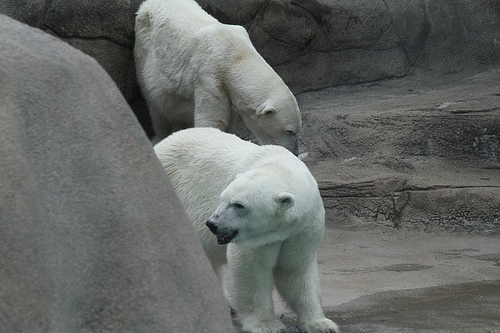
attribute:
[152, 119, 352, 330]
bear — white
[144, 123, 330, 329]
bear — white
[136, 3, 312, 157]
bear — white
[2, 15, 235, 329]
boulder — big, grey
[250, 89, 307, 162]
head — lowered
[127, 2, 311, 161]
polar bear — lowered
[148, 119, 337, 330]
polar bear — pictured, large , white 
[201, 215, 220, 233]
nose — black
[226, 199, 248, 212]
eye — dark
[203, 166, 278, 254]
head — turned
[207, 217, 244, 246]
mouth — open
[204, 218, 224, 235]
bear's nose — black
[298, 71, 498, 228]
steps — rock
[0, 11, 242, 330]
rock — Big 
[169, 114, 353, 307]
bear — polar